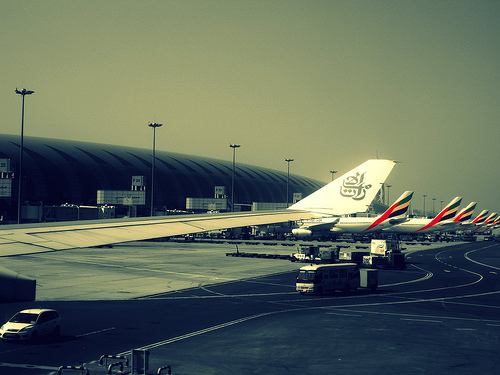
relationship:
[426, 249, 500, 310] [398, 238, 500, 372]
lines on tarmac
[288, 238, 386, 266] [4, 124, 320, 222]
luggage transporter at airport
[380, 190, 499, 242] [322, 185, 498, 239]
tails of planes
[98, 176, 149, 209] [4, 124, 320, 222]
gate at airport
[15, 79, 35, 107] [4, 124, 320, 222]
light at airport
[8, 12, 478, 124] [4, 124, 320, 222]
sky above airport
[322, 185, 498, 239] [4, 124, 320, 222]
planes are parked at airport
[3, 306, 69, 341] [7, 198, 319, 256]
car parked under wing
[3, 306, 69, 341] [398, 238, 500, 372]
car parked on tarmac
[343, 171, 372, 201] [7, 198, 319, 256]
logo on wing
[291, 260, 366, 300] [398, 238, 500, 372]
bus on tarmac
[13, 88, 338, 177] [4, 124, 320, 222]
lights near airport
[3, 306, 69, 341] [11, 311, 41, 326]
car has a windshield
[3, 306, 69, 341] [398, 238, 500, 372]
car on tarmac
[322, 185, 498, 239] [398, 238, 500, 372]
planes are on tarmac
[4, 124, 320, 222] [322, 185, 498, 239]
airport near planes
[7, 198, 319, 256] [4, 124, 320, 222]
wing near airport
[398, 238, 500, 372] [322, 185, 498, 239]
tarmac has planes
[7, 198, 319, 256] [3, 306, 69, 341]
wing above car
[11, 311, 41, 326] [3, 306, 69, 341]
windshield on car